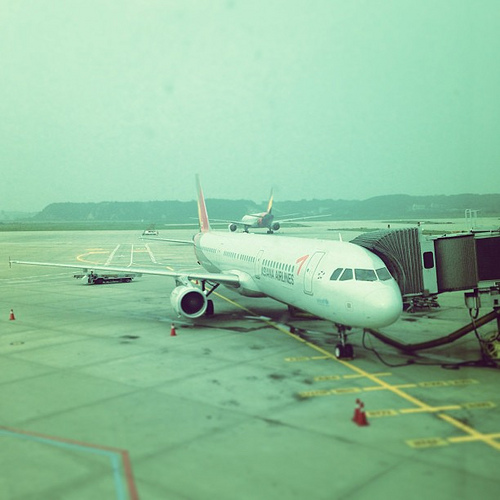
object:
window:
[280, 260, 288, 270]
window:
[329, 265, 339, 287]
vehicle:
[22, 172, 399, 347]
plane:
[0, 173, 404, 363]